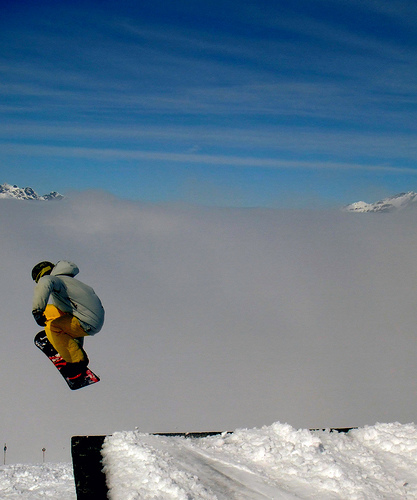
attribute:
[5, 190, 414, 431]
haze — thick cloud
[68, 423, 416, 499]
ramp — black, large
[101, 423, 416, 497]
snow — white, flanky, fluffy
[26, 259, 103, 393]
snowboarder — in air, doing a trick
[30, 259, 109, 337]
sweatshirt — grey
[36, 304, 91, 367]
pants — yellow, gold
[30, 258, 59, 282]
helmet — black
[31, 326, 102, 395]
snowboard — red, black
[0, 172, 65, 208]
mountains — rocky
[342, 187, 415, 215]
mountains — rocky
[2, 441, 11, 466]
sign — black, narrow, in distance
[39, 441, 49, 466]
sign — black, narrow, in distance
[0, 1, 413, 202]
sky — blue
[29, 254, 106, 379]
person — snowboarding, performing a trick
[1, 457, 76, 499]
snow — white, flanky, fluffy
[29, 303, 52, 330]
gloves — black, dark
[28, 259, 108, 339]
jacket — green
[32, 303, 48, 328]
glove — black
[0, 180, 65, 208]
mountain — in background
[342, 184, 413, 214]
mountain — in background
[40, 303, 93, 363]
snowpants — yellow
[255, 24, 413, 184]
clouds — white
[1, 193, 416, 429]
fog — thick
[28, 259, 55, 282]
safety helmet — black